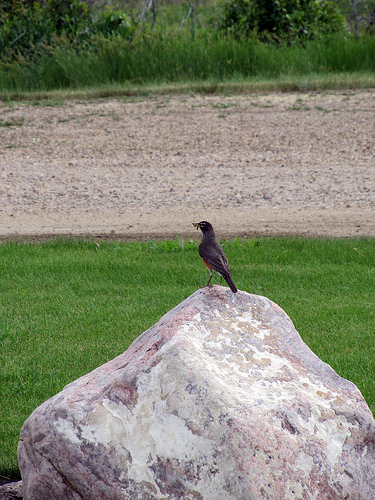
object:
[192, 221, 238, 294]
bird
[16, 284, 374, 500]
rock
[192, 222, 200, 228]
beak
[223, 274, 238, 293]
tail feather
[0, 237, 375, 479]
grass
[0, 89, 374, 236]
road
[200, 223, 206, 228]
eye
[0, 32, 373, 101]
grass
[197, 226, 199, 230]
worm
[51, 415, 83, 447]
speck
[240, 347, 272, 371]
speck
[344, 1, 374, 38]
tree